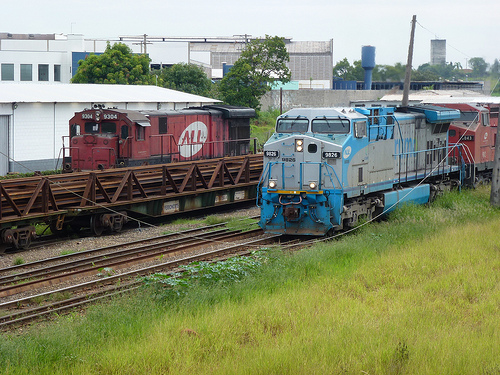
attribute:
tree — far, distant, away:
[466, 55, 492, 74]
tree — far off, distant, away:
[332, 58, 354, 87]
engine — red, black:
[69, 105, 261, 169]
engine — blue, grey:
[258, 103, 462, 223]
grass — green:
[4, 182, 499, 373]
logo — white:
[178, 119, 210, 160]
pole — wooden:
[403, 16, 413, 100]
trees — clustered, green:
[74, 36, 291, 109]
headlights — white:
[267, 142, 318, 195]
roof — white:
[2, 80, 219, 105]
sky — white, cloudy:
[3, 2, 499, 37]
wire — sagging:
[1, 98, 495, 243]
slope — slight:
[303, 193, 499, 285]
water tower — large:
[355, 45, 385, 90]